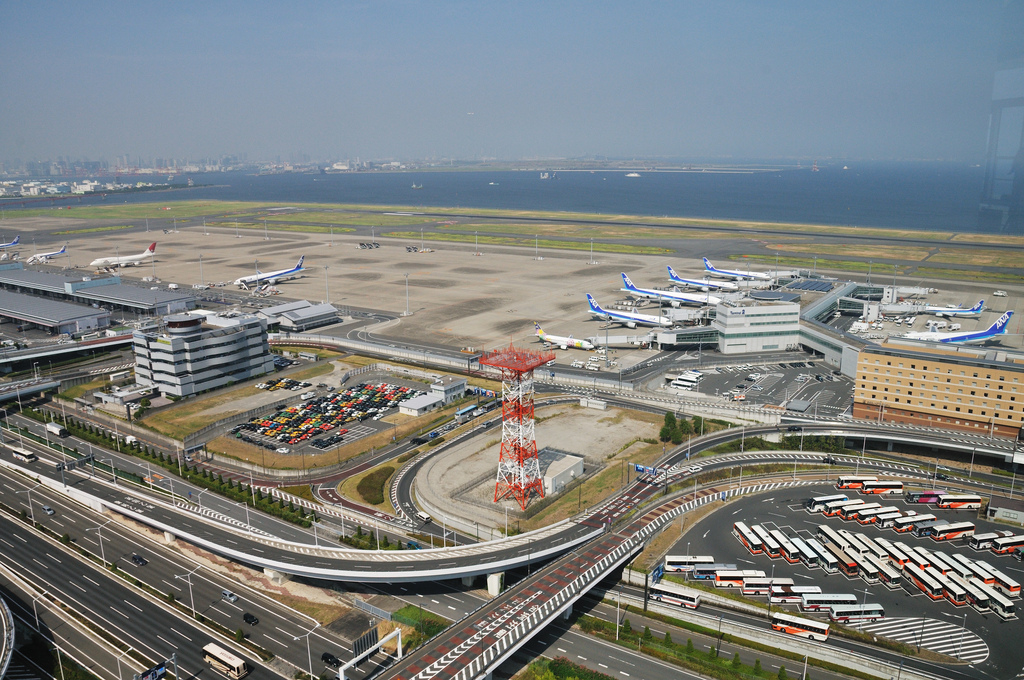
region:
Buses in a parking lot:
[662, 468, 1021, 636]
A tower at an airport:
[476, 341, 552, 515]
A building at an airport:
[127, 310, 277, 399]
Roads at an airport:
[2, 414, 1018, 677]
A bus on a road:
[193, 635, 258, 677]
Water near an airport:
[0, 158, 1022, 235]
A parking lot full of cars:
[228, 372, 412, 459]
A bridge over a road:
[98, 487, 604, 589]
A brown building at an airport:
[849, 341, 1018, 441]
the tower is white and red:
[464, 336, 559, 518]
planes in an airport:
[3, 223, 1022, 669]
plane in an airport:
[571, 287, 680, 339]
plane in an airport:
[615, 270, 733, 310]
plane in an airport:
[691, 248, 777, 284]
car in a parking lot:
[214, 349, 420, 489]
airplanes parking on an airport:
[50, 205, 750, 349]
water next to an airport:
[0, 131, 1023, 370]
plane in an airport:
[887, 306, 1023, 363]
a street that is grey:
[452, 599, 523, 653]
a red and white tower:
[475, 365, 561, 483]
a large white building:
[109, 289, 265, 369]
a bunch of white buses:
[738, 492, 1002, 595]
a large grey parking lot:
[334, 232, 578, 353]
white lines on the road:
[155, 607, 193, 659]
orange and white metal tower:
[465, 335, 571, 516]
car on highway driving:
[228, 603, 267, 632]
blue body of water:
[0, 158, 1022, 238]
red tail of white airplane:
[139, 234, 162, 255]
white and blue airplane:
[575, 284, 680, 338]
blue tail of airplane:
[575, 287, 604, 316]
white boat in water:
[618, 167, 648, 184]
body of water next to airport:
[0, 168, 1021, 229]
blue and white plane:
[228, 250, 305, 285]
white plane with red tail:
[83, 236, 157, 262]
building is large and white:
[133, 301, 280, 394]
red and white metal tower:
[476, 342, 559, 510]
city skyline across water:
[0, 152, 428, 176]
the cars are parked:
[232, 379, 410, 453]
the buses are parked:
[659, 465, 1021, 625]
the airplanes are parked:
[2, 227, 1021, 354]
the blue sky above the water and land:
[2, 0, 1021, 676]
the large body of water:
[2, 157, 1021, 233]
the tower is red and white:
[478, 341, 555, 510]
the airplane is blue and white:
[583, 290, 675, 329]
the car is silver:
[219, 585, 239, 602]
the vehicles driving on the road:
[0, 395, 1022, 677]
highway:
[5, 221, 999, 671]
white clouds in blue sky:
[93, 19, 180, 83]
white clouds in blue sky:
[283, 22, 376, 112]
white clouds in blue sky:
[169, 69, 247, 127]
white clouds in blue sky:
[459, 86, 543, 129]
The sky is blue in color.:
[1, 8, 1022, 171]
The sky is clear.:
[1, 0, 1022, 159]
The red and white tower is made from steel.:
[476, 349, 556, 511]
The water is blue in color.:
[0, 172, 1021, 234]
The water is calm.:
[8, 176, 1017, 235]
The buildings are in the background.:
[5, 153, 438, 180]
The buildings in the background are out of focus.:
[4, 155, 445, 178]